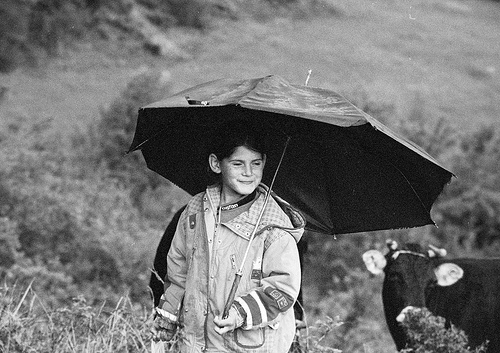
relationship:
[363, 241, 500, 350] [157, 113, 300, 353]
cow next to girl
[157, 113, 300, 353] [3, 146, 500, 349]
girl in front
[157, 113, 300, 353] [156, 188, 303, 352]
girl wearing jacket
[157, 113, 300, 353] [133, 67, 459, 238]
girl holding umbrella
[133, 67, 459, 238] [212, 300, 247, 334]
umbrella in hand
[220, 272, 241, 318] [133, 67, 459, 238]
handle on umbrella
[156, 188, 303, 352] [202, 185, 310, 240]
jacket has hood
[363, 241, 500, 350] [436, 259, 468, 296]
cow has ear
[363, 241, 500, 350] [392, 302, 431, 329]
cow has nose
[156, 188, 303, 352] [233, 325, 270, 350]
jacket has pocket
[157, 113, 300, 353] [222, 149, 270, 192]
girl has face expression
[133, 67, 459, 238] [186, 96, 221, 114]
umbrella has hole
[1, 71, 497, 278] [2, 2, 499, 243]
bushes in background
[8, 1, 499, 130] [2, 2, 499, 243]
grass in background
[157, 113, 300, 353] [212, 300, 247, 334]
girl has hand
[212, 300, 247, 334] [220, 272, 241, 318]
hand on handle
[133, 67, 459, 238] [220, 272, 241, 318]
umbrella has handle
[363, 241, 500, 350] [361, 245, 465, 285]
cow has ears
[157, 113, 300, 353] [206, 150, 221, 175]
girl has ear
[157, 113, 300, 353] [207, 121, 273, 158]
girl has hair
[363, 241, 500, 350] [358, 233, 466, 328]
cow has head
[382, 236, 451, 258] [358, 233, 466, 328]
horns on head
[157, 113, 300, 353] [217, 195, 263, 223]
girl wearing shirt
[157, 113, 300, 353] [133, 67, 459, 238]
girl has umbrella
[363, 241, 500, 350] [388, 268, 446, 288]
cow has eyes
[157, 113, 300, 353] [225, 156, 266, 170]
girl has eyes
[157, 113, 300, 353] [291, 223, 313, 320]
girl wearing backpack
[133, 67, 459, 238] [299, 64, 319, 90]
umbrella has tip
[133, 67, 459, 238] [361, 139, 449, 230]
umbrella has rib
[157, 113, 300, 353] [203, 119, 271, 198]
girl has head